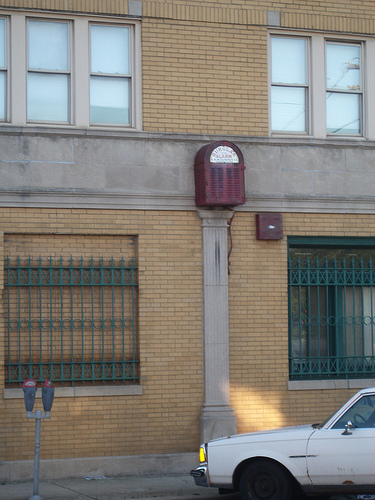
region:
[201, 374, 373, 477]
the car is white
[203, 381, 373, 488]
the car is old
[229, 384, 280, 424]
there is light reflection on the wall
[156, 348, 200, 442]
the wall is made of bricks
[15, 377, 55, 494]
the parking meter is meatllic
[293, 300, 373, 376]
the bars are blue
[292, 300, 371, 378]
the bars are metallic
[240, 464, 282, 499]
the tire is black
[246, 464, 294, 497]
the tire is made of rubber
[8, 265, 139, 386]
the window is closed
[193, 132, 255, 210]
red metal alarm on the building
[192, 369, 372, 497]
old white car parked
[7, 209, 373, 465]
building made of tan brick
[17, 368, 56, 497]
parking meter on metal pole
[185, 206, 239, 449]
stone column decoration on building side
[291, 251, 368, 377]
wrought iron window cover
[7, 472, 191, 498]
concrete sidewalk with a piece of trash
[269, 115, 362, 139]
windows have white window cover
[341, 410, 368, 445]
car has chrome rear view mirror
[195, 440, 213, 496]
car has chrome mirror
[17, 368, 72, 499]
A parking meter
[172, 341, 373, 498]
Half of a white car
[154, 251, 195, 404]
A section of yellow brick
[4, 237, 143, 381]
A bricked up gated window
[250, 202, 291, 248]
A fire alarm box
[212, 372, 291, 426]
Sunshine on a wall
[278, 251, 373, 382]
a window with a green gate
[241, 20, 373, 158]
Two windows on a second floor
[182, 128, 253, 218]
An old fire alarm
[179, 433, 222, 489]
The front light and bumper of a car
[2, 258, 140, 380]
green metal bars on side of building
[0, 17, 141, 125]
windows on side of building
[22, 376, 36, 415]
grey and red parking meter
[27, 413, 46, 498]
grey metal parking meter pole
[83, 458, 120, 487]
trash laying on sidewalk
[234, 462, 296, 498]
black car tire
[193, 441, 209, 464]
headlight on front of car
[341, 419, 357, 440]
silver side view mirror on car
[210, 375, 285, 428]
sun reflecting on wall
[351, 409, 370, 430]
black steering wheel in car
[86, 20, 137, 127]
a long narrow window of a building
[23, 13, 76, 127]
a long narrow window of a building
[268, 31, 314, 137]
a long narrow window of a building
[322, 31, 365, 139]
a long narrow window of a building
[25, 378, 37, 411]
metal top of a parking meter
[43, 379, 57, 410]
metal top of a parking meter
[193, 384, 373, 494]
an old long white car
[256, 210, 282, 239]
a red metal box on a wall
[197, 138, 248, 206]
a red metal box on a wall